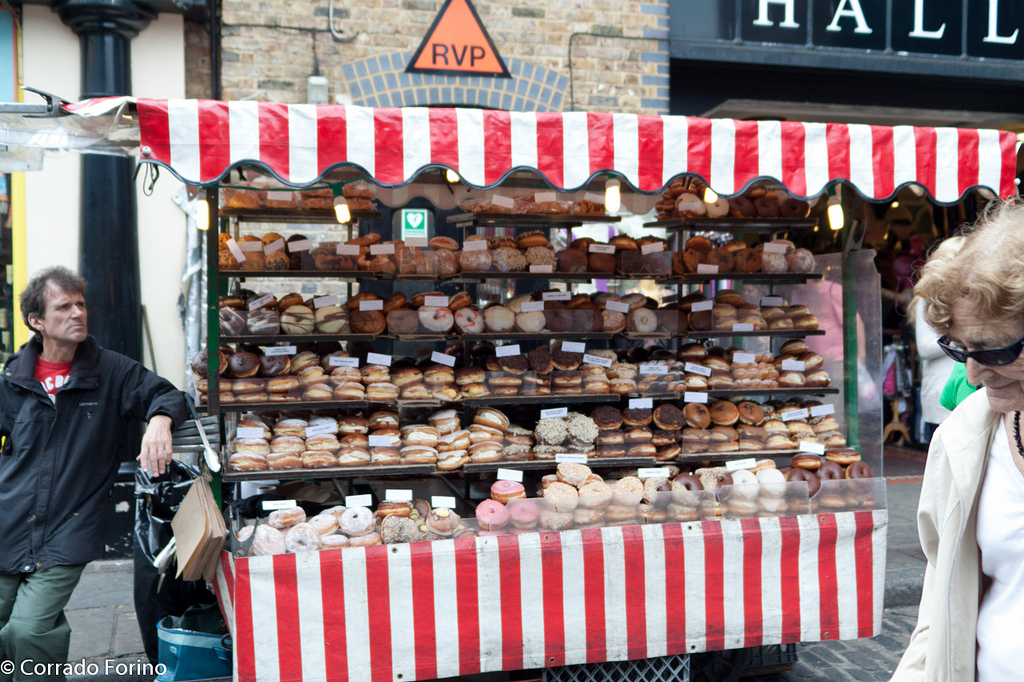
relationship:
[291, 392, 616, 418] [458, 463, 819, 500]
shelf has several doughnuts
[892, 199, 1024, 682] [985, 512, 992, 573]
people wearing a shirt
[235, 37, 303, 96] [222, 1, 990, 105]
wall on side of a building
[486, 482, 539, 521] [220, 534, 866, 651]
donut stacked on cart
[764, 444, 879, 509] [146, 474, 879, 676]
donut stacked on cart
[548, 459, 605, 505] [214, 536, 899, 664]
donut stacked on cart